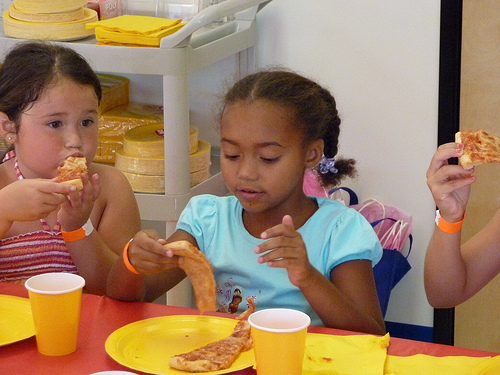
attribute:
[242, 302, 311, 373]
cup — yellow, white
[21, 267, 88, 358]
cup — yellow, white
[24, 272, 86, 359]
cup — yellow, orange, white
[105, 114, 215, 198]
plates — yellow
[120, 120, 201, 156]
paper plates — yellow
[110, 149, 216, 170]
paper plates — yellow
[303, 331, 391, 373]
napkin — yellow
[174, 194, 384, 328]
shirt — blue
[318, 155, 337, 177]
holder — blue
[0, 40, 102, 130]
hair — short, dark brown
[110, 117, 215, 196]
plates — round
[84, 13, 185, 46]
stack — yellow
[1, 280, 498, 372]
tablecloth — red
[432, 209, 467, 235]
bracelet — bright orange, white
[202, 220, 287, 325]
shirt — blue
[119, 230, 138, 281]
wrist band — orange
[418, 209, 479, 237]
band — orange, wrist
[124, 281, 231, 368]
plates — yellow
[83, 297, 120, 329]
table — red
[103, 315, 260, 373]
plate — yellow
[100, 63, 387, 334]
girl — little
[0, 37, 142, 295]
girl — little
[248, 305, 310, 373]
cup — yellow, white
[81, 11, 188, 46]
napkins — orange, square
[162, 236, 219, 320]
pizza — cheese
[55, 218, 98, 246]
band — orange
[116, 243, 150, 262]
bracelet — orange